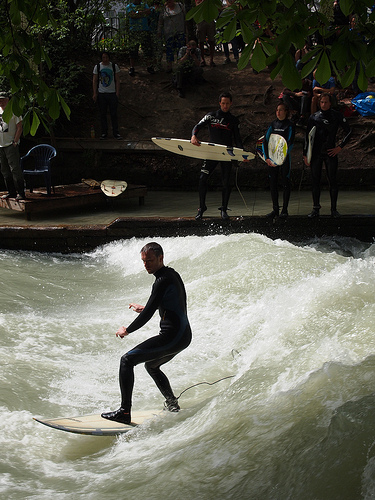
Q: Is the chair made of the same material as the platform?
A: No, the chair is made of plastic and the platform is made of wood.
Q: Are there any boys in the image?
A: No, there are no boys.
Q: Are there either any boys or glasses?
A: No, there are no boys or glasses.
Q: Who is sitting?
A: The man is sitting.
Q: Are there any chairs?
A: Yes, there is a chair.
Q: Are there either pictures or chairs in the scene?
A: Yes, there is a chair.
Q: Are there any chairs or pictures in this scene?
A: Yes, there is a chair.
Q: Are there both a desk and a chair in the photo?
A: No, there is a chair but no desks.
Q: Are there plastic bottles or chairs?
A: Yes, there is a plastic chair.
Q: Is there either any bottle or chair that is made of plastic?
A: Yes, the chair is made of plastic.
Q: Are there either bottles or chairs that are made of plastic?
A: Yes, the chair is made of plastic.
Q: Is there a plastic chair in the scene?
A: Yes, there is a chair that is made of plastic.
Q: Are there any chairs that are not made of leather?
A: Yes, there is a chair that is made of plastic.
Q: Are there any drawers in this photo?
A: No, there are no drawers.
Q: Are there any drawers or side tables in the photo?
A: No, there are no drawers or side tables.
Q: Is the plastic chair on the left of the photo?
A: Yes, the chair is on the left of the image.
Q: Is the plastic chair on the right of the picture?
A: No, the chair is on the left of the image.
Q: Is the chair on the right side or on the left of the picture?
A: The chair is on the left of the image.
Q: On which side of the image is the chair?
A: The chair is on the left of the image.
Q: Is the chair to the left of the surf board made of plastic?
A: Yes, the chair is made of plastic.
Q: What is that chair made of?
A: The chair is made of plastic.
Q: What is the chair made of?
A: The chair is made of plastic.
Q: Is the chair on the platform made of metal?
A: No, the chair is made of plastic.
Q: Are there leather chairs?
A: No, there is a chair but it is made of plastic.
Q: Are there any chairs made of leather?
A: No, there is a chair but it is made of plastic.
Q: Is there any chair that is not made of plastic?
A: No, there is a chair but it is made of plastic.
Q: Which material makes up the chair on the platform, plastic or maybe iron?
A: The chair is made of plastic.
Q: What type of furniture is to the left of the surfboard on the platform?
A: The piece of furniture is a chair.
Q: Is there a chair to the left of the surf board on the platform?
A: Yes, there is a chair to the left of the surf board.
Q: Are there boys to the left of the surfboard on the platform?
A: No, there is a chair to the left of the surfboard.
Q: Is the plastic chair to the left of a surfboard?
A: Yes, the chair is to the left of a surfboard.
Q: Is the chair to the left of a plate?
A: No, the chair is to the left of a surfboard.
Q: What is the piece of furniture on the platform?
A: The piece of furniture is a chair.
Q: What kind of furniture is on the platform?
A: The piece of furniture is a chair.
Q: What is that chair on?
A: The chair is on the platform.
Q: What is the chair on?
A: The chair is on the platform.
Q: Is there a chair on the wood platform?
A: Yes, there is a chair on the platform.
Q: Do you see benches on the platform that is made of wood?
A: No, there is a chair on the platform.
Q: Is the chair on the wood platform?
A: Yes, the chair is on the platform.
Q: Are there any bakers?
A: No, there are no bakers.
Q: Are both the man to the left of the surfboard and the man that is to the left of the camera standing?
A: Yes, both the man and the man are standing.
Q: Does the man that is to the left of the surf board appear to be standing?
A: Yes, the man is standing.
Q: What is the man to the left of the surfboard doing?
A: The man is standing.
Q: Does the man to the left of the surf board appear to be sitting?
A: No, the man is standing.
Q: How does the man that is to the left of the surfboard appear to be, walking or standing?
A: The man is standing.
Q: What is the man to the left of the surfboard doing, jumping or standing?
A: The man is standing.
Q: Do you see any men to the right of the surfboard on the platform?
A: Yes, there is a man to the right of the surfboard.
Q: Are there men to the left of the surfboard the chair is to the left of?
A: No, the man is to the right of the surf board.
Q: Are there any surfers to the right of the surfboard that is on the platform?
A: No, there is a man to the right of the surfboard.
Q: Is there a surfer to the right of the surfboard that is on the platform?
A: No, there is a man to the right of the surfboard.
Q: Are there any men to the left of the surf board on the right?
A: Yes, there is a man to the left of the surfboard.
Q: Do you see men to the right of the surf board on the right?
A: No, the man is to the left of the surfboard.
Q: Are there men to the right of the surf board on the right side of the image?
A: No, the man is to the left of the surfboard.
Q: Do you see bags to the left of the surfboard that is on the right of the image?
A: No, there is a man to the left of the surfboard.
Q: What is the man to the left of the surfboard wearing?
A: The man is wearing a wetsuit.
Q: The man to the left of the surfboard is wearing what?
A: The man is wearing a wetsuit.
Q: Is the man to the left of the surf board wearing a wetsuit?
A: Yes, the man is wearing a wetsuit.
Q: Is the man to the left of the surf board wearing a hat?
A: No, the man is wearing a wetsuit.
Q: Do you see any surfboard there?
A: Yes, there is a surfboard.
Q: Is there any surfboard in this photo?
A: Yes, there is a surfboard.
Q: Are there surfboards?
A: Yes, there is a surfboard.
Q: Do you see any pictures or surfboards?
A: Yes, there is a surfboard.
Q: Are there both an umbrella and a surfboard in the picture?
A: No, there is a surfboard but no umbrellas.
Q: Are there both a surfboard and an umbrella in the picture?
A: No, there is a surfboard but no umbrellas.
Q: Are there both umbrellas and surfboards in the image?
A: No, there is a surfboard but no umbrellas.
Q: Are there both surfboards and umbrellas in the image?
A: No, there is a surfboard but no umbrellas.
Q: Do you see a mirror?
A: No, there are no mirrors.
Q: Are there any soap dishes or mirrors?
A: No, there are no mirrors or soap dishes.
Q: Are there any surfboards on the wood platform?
A: Yes, there is a surfboard on the platform.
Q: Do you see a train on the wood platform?
A: No, there is a surfboard on the platform.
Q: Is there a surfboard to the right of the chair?
A: Yes, there is a surfboard to the right of the chair.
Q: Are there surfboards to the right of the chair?
A: Yes, there is a surfboard to the right of the chair.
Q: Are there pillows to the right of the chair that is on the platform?
A: No, there is a surfboard to the right of the chair.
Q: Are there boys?
A: No, there are no boys.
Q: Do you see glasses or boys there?
A: No, there are no boys or glasses.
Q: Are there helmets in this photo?
A: No, there are no helmets.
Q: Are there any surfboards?
A: Yes, there is a surfboard.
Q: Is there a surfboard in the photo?
A: Yes, there is a surfboard.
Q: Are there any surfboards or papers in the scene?
A: Yes, there is a surfboard.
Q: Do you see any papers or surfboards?
A: Yes, there is a surfboard.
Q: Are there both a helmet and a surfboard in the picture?
A: No, there is a surfboard but no helmets.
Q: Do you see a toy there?
A: No, there are no toys.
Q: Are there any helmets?
A: No, there are no helmets.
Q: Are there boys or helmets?
A: No, there are no helmets or boys.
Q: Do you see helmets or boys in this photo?
A: No, there are no helmets or boys.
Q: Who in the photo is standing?
A: The man is standing.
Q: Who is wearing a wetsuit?
A: The man is wearing a wetsuit.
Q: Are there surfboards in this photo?
A: Yes, there is a surfboard.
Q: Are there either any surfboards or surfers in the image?
A: Yes, there is a surfboard.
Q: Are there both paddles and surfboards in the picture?
A: No, there is a surfboard but no paddles.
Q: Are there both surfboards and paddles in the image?
A: No, there is a surfboard but no paddles.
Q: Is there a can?
A: No, there are no cans.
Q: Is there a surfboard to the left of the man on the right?
A: Yes, there is a surfboard to the left of the man.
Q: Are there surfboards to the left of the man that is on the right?
A: Yes, there is a surfboard to the left of the man.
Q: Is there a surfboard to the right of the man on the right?
A: No, the surfboard is to the left of the man.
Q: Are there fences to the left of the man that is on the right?
A: No, there is a surfboard to the left of the man.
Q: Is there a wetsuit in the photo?
A: Yes, there is a wetsuit.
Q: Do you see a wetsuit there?
A: Yes, there is a wetsuit.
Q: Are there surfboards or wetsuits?
A: Yes, there is a wetsuit.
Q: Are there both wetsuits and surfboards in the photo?
A: Yes, there are both a wetsuit and a surfboard.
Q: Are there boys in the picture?
A: No, there are no boys.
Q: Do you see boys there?
A: No, there are no boys.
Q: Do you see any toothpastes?
A: No, there are no toothpastes.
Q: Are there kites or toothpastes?
A: No, there are no toothpastes or kites.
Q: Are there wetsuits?
A: Yes, there is a wetsuit.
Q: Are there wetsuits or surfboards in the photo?
A: Yes, there is a wetsuit.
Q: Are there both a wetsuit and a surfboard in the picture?
A: Yes, there are both a wetsuit and a surfboard.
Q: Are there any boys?
A: No, there are no boys.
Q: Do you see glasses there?
A: No, there are no glasses.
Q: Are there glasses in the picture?
A: No, there are no glasses.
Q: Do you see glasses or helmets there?
A: No, there are no glasses or helmets.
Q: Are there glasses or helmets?
A: No, there are no glasses or helmets.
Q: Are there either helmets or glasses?
A: No, there are no glasses or helmets.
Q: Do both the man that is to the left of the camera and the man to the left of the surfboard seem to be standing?
A: Yes, both the man and the man are standing.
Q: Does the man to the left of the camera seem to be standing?
A: Yes, the man is standing.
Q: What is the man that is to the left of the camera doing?
A: The man is standing.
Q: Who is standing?
A: The man is standing.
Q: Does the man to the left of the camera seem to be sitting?
A: No, the man is standing.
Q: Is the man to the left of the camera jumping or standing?
A: The man is standing.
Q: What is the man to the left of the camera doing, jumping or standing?
A: The man is standing.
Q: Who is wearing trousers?
A: The man is wearing trousers.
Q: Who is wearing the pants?
A: The man is wearing trousers.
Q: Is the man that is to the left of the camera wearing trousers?
A: Yes, the man is wearing trousers.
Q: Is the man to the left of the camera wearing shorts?
A: No, the man is wearing trousers.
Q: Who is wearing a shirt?
A: The man is wearing a shirt.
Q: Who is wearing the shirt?
A: The man is wearing a shirt.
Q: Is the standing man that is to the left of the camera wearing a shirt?
A: Yes, the man is wearing a shirt.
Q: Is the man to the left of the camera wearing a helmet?
A: No, the man is wearing a shirt.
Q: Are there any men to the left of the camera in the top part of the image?
A: Yes, there is a man to the left of the camera.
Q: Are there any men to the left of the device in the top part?
A: Yes, there is a man to the left of the camera.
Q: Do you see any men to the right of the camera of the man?
A: No, the man is to the left of the camera.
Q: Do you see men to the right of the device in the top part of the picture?
A: No, the man is to the left of the camera.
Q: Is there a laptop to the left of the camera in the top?
A: No, there is a man to the left of the camera.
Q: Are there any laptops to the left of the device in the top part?
A: No, there is a man to the left of the camera.